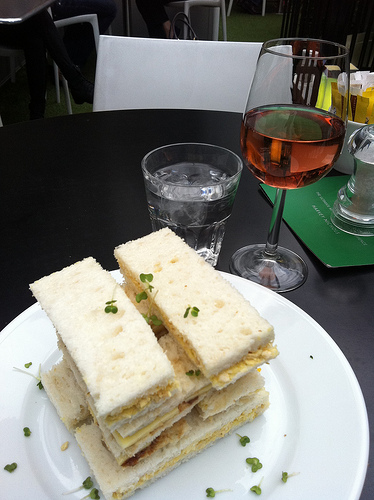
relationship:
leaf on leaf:
[115, 264, 188, 306] [135, 273, 153, 303]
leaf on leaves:
[100, 273, 161, 316] [185, 370, 200, 376]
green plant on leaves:
[4, 461, 17, 471] [185, 370, 200, 376]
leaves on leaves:
[236, 433, 250, 447] [185, 370, 200, 376]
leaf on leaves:
[246, 457, 262, 471] [185, 370, 200, 376]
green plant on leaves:
[250, 485, 262, 494] [185, 370, 200, 376]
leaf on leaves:
[206, 487, 216, 496] [185, 370, 200, 376]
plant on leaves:
[280, 471, 289, 481] [185, 370, 200, 376]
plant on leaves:
[73, 476, 101, 498] [185, 370, 200, 376]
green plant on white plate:
[233, 433, 290, 496] [273, 370, 367, 467]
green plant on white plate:
[4, 421, 33, 475] [3, 321, 47, 355]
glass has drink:
[228, 31, 355, 298] [243, 101, 342, 185]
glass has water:
[137, 135, 244, 268] [127, 137, 253, 263]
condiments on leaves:
[330, 66, 373, 123] [185, 370, 200, 376]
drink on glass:
[240, 104, 346, 190] [228, 31, 355, 298]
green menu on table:
[260, 173, 373, 269] [3, 104, 371, 498]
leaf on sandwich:
[183, 306, 200, 318] [28, 227, 277, 498]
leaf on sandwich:
[104, 299, 117, 314] [28, 227, 277, 498]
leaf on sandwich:
[135, 273, 153, 303] [28, 227, 277, 498]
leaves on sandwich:
[182, 366, 201, 375] [28, 227, 277, 498]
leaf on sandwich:
[141, 313, 163, 326] [28, 227, 277, 498]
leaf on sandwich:
[246, 457, 262, 471] [28, 227, 277, 498]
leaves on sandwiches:
[234, 433, 266, 470] [36, 264, 253, 496]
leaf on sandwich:
[203, 483, 214, 494] [30, 257, 174, 414]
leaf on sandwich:
[182, 303, 200, 320] [115, 223, 274, 389]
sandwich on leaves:
[28, 227, 277, 498] [185, 370, 200, 376]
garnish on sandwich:
[180, 301, 202, 318] [110, 221, 283, 393]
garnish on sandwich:
[180, 301, 202, 318] [28, 227, 277, 498]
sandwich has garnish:
[28, 227, 277, 498] [180, 301, 202, 318]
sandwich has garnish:
[110, 221, 283, 393] [180, 301, 202, 318]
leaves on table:
[185, 370, 200, 376] [0, 109, 374, 498]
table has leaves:
[0, 109, 374, 498] [185, 370, 200, 376]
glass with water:
[140, 143, 243, 267] [148, 161, 234, 271]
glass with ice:
[140, 143, 243, 267] [205, 165, 225, 178]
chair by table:
[87, 33, 306, 117] [0, 115, 363, 394]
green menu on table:
[260, 173, 373, 273] [3, 104, 371, 498]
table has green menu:
[3, 104, 371, 498] [260, 173, 373, 273]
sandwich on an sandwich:
[28, 227, 277, 498] [28, 227, 277, 498]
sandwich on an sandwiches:
[28, 227, 277, 498] [197, 371, 267, 424]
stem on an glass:
[264, 180, 289, 261] [228, 38, 350, 292]